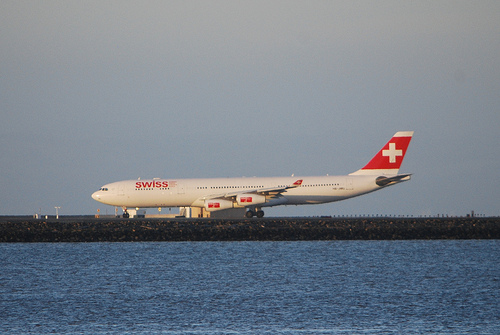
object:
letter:
[136, 180, 169, 188]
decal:
[208, 202, 221, 208]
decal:
[240, 197, 253, 203]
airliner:
[90, 131, 414, 219]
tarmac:
[72, 213, 373, 237]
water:
[0, 243, 489, 326]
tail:
[350, 131, 415, 197]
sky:
[9, 0, 384, 174]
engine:
[236, 194, 266, 206]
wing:
[207, 179, 303, 200]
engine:
[204, 199, 233, 212]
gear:
[256, 211, 264, 218]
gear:
[123, 213, 130, 219]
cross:
[382, 142, 404, 163]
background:
[377, 104, 422, 179]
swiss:
[136, 180, 169, 188]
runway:
[2, 215, 187, 226]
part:
[246, 210, 254, 218]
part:
[236, 193, 265, 206]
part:
[377, 173, 413, 186]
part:
[348, 131, 415, 175]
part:
[92, 175, 373, 207]